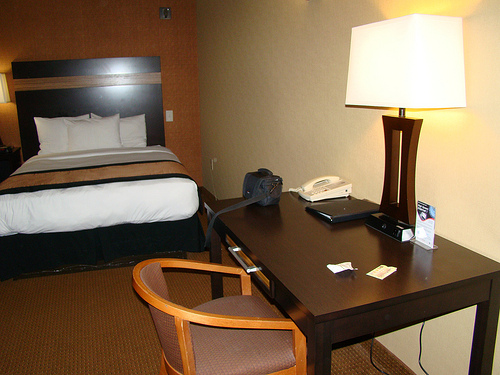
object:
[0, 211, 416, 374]
carpet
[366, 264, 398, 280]
notebook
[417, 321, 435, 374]
cord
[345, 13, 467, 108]
white lampshade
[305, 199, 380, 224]
folder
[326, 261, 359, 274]
paper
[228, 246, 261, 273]
handle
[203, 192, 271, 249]
cord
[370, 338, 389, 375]
cord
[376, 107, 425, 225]
base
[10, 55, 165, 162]
head board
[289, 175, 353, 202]
phone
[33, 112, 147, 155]
pillows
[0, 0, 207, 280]
bed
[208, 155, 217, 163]
outlet.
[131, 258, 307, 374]
chair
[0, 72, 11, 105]
lamp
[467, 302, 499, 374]
leg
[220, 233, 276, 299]
drawer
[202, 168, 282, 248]
camera bag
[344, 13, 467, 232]
display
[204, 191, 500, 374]
nightstand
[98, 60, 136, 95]
light